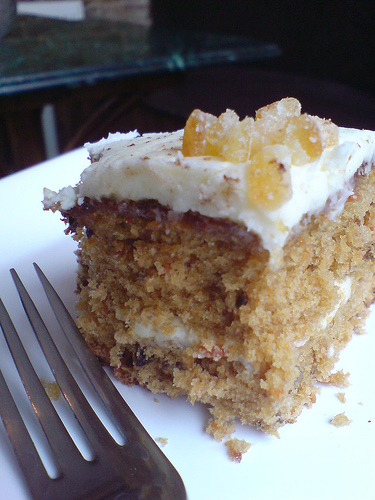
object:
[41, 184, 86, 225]
piece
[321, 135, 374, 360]
cake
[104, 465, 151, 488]
silver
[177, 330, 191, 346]
thin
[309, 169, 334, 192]
frosting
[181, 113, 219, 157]
yellow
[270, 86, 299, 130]
topping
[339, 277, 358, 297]
midlayer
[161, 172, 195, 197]
white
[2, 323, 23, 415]
fork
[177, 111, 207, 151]
fruit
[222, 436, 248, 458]
crumbs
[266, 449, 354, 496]
plate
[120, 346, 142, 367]
raisins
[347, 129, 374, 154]
cream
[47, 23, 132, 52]
table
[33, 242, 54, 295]
edge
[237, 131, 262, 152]
potato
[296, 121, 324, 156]
crunch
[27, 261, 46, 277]
edge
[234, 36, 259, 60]
part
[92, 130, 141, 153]
edge